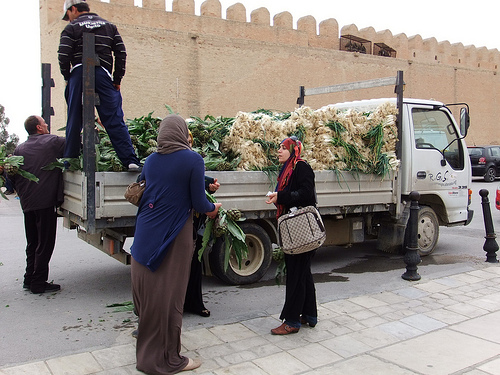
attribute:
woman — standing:
[266, 132, 328, 340]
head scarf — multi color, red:
[280, 138, 308, 193]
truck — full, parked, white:
[65, 90, 481, 276]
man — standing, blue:
[52, 0, 139, 172]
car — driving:
[470, 146, 499, 187]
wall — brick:
[155, 21, 309, 96]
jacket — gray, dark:
[16, 135, 63, 209]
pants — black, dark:
[19, 207, 59, 286]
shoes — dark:
[20, 280, 67, 296]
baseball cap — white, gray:
[59, 0, 91, 22]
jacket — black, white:
[56, 14, 131, 88]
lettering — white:
[74, 18, 115, 34]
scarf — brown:
[154, 114, 196, 156]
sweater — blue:
[130, 150, 212, 271]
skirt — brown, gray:
[134, 217, 190, 372]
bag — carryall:
[275, 203, 327, 254]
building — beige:
[120, 2, 347, 102]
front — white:
[378, 100, 484, 270]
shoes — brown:
[269, 321, 300, 337]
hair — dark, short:
[21, 114, 44, 137]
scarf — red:
[267, 134, 308, 199]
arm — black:
[264, 166, 318, 213]